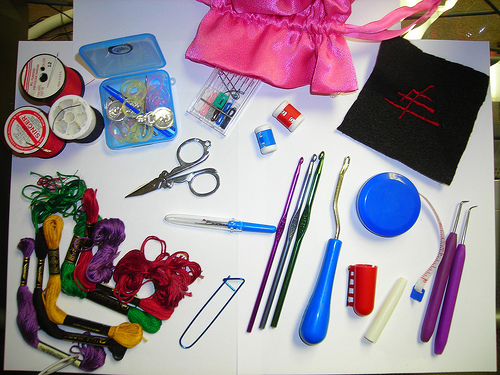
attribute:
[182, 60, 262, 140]
sewing kit — small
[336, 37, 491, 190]
bag — little, letters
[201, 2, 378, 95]
clothe — shiny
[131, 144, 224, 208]
scissors — one pair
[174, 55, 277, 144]
case — clear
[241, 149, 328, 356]
hooks — three, lined up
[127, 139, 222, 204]
scissors — metal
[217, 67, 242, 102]
pin — safety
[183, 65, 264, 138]
box — clear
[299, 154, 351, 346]
hook — latch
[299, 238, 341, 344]
handle — blue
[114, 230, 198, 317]
string — different colors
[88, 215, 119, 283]
string — different colors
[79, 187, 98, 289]
string — different colors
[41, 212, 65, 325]
string — different colors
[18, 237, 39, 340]
string — different colors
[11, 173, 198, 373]
string — colored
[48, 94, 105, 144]
spool — thread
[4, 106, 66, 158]
spool — thread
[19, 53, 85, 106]
spool — thread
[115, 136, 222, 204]
metal scissors — small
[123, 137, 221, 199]
shears — silver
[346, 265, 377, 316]
thimble — red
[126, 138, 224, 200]
scisors — small, pair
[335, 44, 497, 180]
cloth — black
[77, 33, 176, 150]
box — blue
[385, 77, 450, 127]
japanese letters — red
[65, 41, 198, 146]
container — blue, open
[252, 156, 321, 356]
needles — knitting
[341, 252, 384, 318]
thimble — red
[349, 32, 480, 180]
fabric — black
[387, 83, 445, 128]
stitching — red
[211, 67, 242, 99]
pin — safety